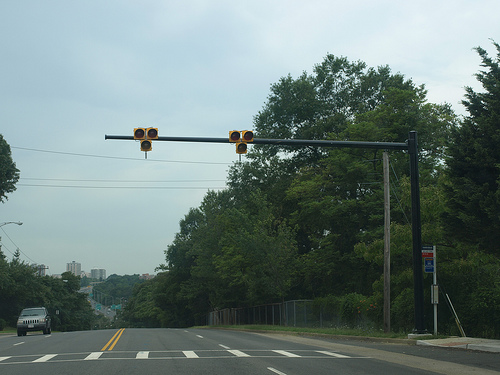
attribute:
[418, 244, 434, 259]
sign — red, blue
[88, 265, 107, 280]
buildings — distant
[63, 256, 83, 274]
buildings — distant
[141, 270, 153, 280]
buildings — distant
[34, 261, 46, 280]
buildings — distant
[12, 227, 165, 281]
distance — distant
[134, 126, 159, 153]
light — fixture, yellow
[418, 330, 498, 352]
sidewalk — concrete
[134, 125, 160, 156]
light — street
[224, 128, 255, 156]
light — street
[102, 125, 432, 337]
pole — metal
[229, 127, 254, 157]
traffic signal — yellow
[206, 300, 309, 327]
fencing — steel 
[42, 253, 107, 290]
buildings — tall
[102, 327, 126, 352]
line — yellow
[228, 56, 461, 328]
green tree —  very large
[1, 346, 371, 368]
sign — pedestrian cross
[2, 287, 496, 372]
long road — empty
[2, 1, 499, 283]
overcast skies — gray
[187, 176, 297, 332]
green tree —  very large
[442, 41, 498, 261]
green tree —  very large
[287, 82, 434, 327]
green tree —  very large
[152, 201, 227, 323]
green tree —  very large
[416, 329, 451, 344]
base — small, concrete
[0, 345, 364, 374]
crossing — pedestrian crossing